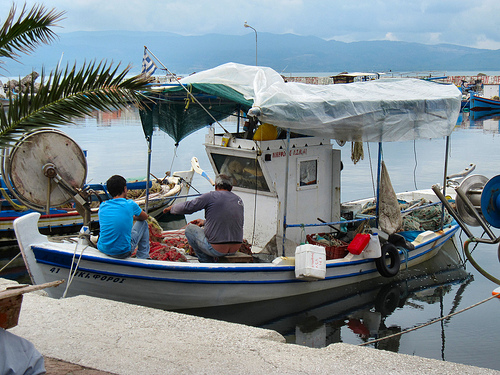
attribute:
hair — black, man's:
[103, 171, 124, 196]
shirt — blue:
[96, 198, 138, 255]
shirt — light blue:
[100, 196, 137, 255]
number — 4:
[45, 265, 58, 275]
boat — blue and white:
[24, 59, 467, 307]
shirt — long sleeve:
[99, 190, 153, 265]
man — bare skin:
[163, 173, 245, 261]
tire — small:
[376, 242, 401, 277]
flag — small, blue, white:
[137, 45, 157, 80]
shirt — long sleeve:
[188, 191, 240, 243]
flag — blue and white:
[126, 41, 166, 93]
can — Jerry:
[292, 232, 341, 296]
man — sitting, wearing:
[158, 170, 245, 266]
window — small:
[276, 147, 348, 215]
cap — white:
[215, 172, 228, 186]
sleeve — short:
[132, 197, 142, 215]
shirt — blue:
[96, 196, 142, 256]